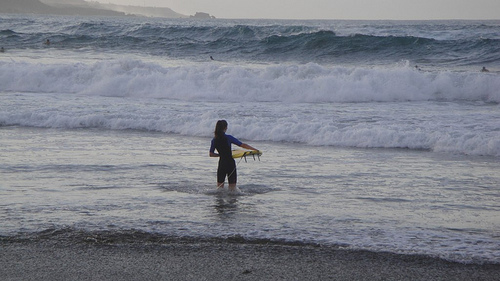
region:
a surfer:
[199, 112, 269, 206]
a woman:
[200, 113, 264, 196]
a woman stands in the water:
[202, 113, 265, 205]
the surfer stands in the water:
[199, 112, 281, 198]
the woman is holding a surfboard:
[199, 114, 267, 215]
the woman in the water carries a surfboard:
[186, 106, 267, 199]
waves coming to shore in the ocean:
[20, 13, 498, 278]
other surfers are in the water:
[31, 24, 497, 91]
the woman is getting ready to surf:
[186, 100, 277, 220]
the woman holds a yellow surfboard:
[194, 106, 286, 216]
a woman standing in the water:
[136, 85, 386, 276]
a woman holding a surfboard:
[149, 61, 272, 276]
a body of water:
[308, 82, 493, 152]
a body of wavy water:
[367, 39, 444, 243]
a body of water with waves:
[307, 20, 444, 181]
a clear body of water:
[297, 25, 404, 139]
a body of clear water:
[262, 25, 456, 275]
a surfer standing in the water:
[147, 93, 391, 233]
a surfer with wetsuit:
[153, 89, 373, 231]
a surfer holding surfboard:
[169, 49, 355, 279]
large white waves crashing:
[291, 68, 342, 106]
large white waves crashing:
[163, 84, 194, 106]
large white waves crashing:
[74, 75, 110, 110]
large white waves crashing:
[423, 76, 461, 103]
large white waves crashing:
[343, 84, 371, 104]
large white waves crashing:
[312, 62, 352, 92]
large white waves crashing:
[61, 61, 105, 96]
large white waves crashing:
[289, 50, 326, 74]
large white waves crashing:
[323, 20, 361, 52]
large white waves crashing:
[54, 65, 86, 96]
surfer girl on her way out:
[195, 110, 248, 190]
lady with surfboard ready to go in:
[180, 115, 255, 206]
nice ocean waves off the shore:
[10, 0, 495, 120]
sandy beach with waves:
[0, 237, 480, 277]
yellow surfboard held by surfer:
[220, 141, 275, 166]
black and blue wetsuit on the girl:
[202, 127, 238, 188]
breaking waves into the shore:
[0, 60, 480, 103]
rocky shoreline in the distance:
[0, 3, 221, 24]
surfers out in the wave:
[391, 57, 488, 87]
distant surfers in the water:
[0, 24, 76, 58]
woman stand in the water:
[194, 107, 267, 195]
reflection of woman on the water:
[204, 185, 251, 225]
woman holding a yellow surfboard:
[194, 111, 266, 199]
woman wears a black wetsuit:
[194, 111, 269, 192]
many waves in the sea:
[7, 3, 488, 125]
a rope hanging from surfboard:
[208, 148, 255, 193]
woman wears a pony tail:
[203, 111, 265, 197]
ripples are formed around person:
[159, 171, 289, 203]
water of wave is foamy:
[7, 50, 495, 102]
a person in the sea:
[467, 59, 497, 79]